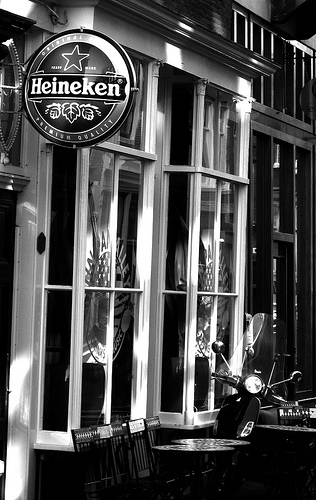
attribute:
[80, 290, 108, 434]
pane — white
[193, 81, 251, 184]
trim — wooden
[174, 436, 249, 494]
table — small, round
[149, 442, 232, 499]
table — small, round